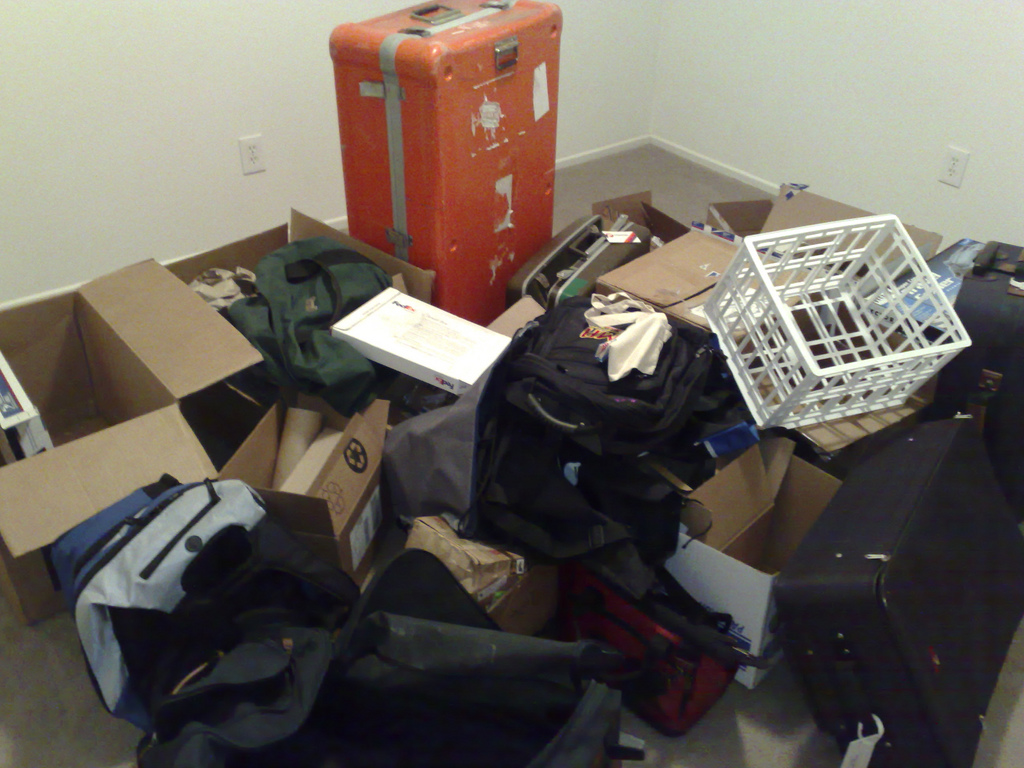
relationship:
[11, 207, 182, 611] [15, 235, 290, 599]
box on ground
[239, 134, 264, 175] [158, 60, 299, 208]
electrical plug apart of wall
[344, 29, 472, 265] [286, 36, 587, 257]
stripe on box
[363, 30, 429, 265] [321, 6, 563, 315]
stripe on box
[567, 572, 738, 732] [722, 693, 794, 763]
hand bag on floor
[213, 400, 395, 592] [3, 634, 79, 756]
box on floor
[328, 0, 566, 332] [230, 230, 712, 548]
box next to pile of bags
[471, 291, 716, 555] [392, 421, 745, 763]
black bag on pile of bags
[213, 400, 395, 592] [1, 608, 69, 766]
box on floor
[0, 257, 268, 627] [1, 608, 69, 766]
box on floor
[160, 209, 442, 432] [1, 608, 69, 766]
boxes on floor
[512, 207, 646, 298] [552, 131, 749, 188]
brown suitcase on floor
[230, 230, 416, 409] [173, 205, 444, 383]
bags on top of box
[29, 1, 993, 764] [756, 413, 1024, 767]
room filled with bag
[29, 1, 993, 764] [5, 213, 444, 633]
room filled with boxes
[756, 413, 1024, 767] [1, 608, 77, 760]
bag on floor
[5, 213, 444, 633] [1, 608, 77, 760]
boxes on floor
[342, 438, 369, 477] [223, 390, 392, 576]
recycle sign on box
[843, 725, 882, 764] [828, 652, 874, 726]
white tag on handle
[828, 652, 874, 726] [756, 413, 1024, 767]
handle of bag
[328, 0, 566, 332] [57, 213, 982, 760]
box behind pile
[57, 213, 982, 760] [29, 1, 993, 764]
pile in room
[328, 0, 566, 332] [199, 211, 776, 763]
box behind pile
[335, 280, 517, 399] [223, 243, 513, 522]
shipping box on pile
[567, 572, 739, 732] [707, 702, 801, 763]
hand bag on ground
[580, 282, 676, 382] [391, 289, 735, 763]
paper on pile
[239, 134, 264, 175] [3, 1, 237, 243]
electrical plug on wall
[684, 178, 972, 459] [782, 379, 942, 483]
plastic on box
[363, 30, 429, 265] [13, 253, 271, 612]
stripe on box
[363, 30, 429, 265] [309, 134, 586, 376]
stripe on box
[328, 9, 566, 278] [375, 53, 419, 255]
box has a stripe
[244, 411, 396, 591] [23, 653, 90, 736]
box on floor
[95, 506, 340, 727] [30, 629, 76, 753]
bag on floor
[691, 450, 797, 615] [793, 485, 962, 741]
box on side of suitcase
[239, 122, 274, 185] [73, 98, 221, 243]
electrical plug on wall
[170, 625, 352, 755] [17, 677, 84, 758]
bag on floor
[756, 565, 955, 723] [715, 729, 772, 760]
bag on floor